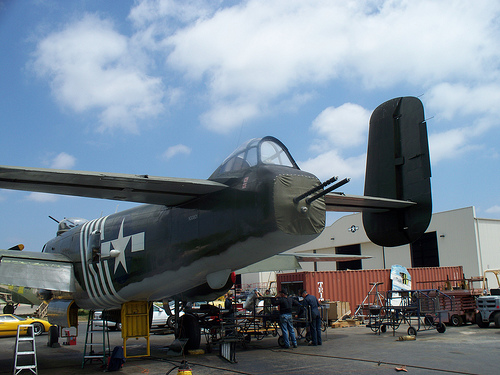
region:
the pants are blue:
[280, 314, 304, 341]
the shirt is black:
[272, 294, 297, 311]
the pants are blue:
[308, 319, 325, 342]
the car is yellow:
[3, 311, 45, 338]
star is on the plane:
[91, 222, 142, 284]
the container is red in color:
[310, 265, 469, 321]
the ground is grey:
[335, 329, 400, 374]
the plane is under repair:
[1, 95, 421, 307]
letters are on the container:
[316, 279, 326, 295]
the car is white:
[96, 304, 187, 333]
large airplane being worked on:
[0, 91, 455, 321]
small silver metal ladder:
[5, 322, 40, 374]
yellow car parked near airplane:
[0, 305, 53, 340]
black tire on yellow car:
[24, 318, 47, 339]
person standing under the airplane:
[264, 287, 301, 353]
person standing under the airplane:
[298, 286, 327, 348]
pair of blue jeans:
[277, 312, 302, 347]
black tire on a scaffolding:
[402, 324, 416, 336]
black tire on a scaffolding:
[432, 321, 447, 336]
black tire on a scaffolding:
[378, 323, 389, 334]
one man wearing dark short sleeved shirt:
[276, 286, 301, 351]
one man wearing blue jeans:
[276, 287, 298, 349]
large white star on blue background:
[104, 216, 137, 280]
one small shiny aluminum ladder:
[9, 319, 41, 374]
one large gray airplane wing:
[2, 157, 230, 216]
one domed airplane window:
[222, 132, 302, 177]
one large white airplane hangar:
[311, 204, 498, 304]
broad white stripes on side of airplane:
[75, 215, 123, 317]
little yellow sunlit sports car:
[1, 311, 53, 340]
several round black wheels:
[377, 313, 472, 340]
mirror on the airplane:
[339, 94, 462, 255]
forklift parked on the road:
[356, 270, 498, 345]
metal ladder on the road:
[10, 316, 35, 373]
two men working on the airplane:
[276, 281, 328, 349]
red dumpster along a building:
[306, 262, 485, 289]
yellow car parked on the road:
[0, 308, 55, 335]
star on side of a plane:
[104, 219, 141, 274]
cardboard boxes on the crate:
[326, 295, 361, 320]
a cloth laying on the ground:
[382, 358, 417, 373]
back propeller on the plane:
[44, 209, 89, 231]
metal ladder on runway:
[6, 317, 50, 373]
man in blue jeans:
[270, 287, 305, 353]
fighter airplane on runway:
[0, 104, 438, 323]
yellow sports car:
[1, 309, 52, 340]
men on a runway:
[251, 283, 331, 359]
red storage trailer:
[279, 263, 470, 323]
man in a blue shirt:
[299, 287, 327, 345]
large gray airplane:
[6, 123, 422, 325]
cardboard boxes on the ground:
[318, 294, 358, 325]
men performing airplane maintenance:
[258, 283, 332, 358]